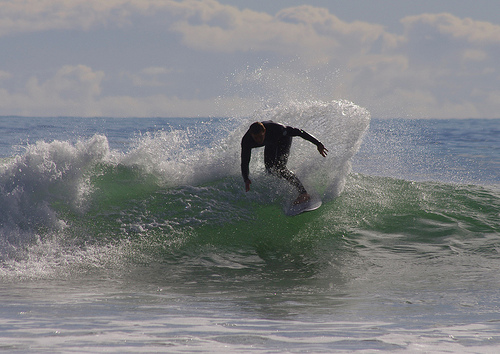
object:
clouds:
[1, 0, 498, 117]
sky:
[0, 1, 497, 120]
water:
[1, 94, 498, 351]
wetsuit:
[241, 120, 318, 194]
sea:
[1, 116, 500, 348]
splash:
[0, 99, 497, 276]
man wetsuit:
[239, 119, 326, 205]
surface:
[3, 117, 495, 198]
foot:
[292, 191, 309, 205]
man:
[241, 120, 330, 204]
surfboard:
[284, 177, 322, 216]